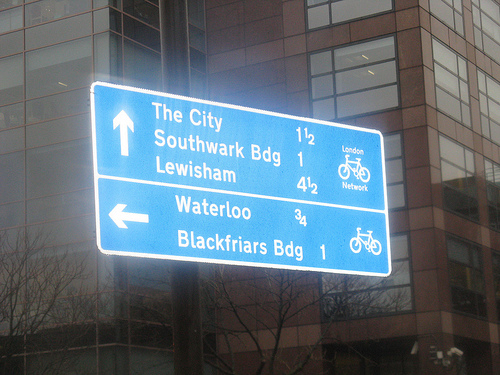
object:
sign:
[340, 180, 369, 192]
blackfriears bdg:
[178, 230, 304, 262]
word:
[148, 128, 282, 168]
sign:
[295, 175, 317, 196]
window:
[334, 45, 383, 69]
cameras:
[410, 334, 464, 371]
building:
[202, 0, 500, 375]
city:
[152, 101, 223, 132]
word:
[187, 105, 225, 134]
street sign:
[89, 81, 392, 278]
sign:
[291, 207, 307, 227]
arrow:
[111, 109, 134, 156]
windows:
[303, 34, 399, 121]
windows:
[429, 34, 471, 128]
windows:
[476, 68, 498, 144]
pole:
[168, 260, 205, 374]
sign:
[295, 126, 316, 145]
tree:
[144, 259, 414, 374]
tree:
[3, 225, 120, 374]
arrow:
[108, 203, 150, 228]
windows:
[440, 133, 487, 227]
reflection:
[58, 279, 107, 322]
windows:
[298, 26, 415, 109]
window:
[320, 235, 412, 320]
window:
[380, 128, 406, 208]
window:
[430, 35, 472, 128]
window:
[445, 235, 487, 319]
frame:
[304, 0, 392, 30]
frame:
[317, 233, 415, 321]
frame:
[445, 235, 489, 320]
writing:
[165, 190, 323, 267]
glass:
[24, 48, 90, 91]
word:
[151, 152, 238, 183]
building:
[0, 0, 178, 375]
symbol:
[349, 227, 382, 255]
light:
[108, 181, 131, 200]